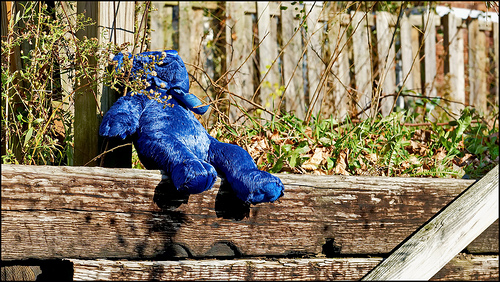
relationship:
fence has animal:
[228, 10, 470, 113] [91, 35, 285, 210]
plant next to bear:
[7, 18, 124, 156] [91, 35, 285, 210]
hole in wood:
[303, 18, 361, 179] [35, 171, 443, 281]